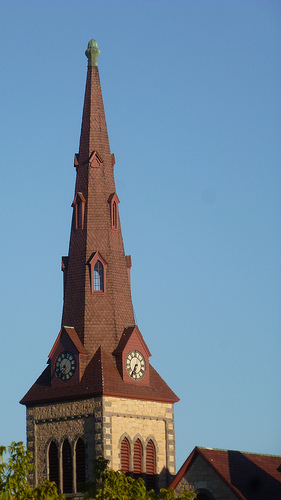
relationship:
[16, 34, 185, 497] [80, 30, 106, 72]
clock tower has top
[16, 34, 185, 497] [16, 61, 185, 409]
clock tower has brown steeple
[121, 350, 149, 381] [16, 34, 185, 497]
clock in clock tower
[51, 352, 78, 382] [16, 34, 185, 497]
clock in clock tower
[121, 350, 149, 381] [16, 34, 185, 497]
clock outside of tower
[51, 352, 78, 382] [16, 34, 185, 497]
clock outside of tower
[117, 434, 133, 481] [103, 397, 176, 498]
window attached to wall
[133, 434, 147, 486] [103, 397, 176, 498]
window attached to wall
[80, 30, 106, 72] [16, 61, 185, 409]
top of roof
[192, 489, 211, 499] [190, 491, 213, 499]
part of a window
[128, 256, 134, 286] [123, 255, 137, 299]
edge of window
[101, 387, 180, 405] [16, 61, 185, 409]
edge of roof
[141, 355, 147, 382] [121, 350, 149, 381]
edge of a clock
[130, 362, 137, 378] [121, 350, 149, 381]
part of a clock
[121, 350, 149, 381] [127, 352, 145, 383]
clock with roman numerals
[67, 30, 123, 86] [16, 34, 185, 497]
top of clock tower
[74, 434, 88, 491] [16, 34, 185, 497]
red vent on side of building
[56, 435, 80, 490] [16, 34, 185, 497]
red vent on side of building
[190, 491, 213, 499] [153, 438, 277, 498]
window on top of building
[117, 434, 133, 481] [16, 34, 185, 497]
vent on side of building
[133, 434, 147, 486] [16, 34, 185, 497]
vent on side of building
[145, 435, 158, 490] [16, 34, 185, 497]
vent on side of building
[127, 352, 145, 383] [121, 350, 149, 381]
black writing on outside of clock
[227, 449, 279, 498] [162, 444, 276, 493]
shadow on roof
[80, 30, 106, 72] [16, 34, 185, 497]
top of building